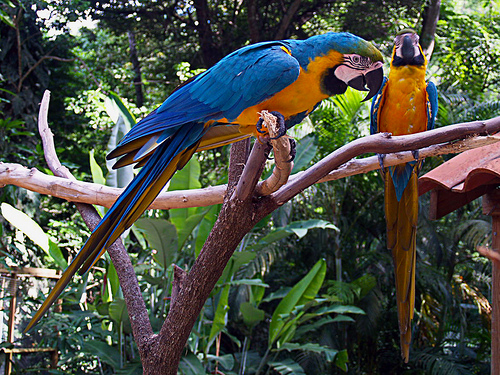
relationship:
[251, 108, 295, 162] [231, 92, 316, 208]
talons holding onto branch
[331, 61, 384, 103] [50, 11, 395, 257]
beak of parrott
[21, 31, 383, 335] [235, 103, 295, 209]
bird perched on branch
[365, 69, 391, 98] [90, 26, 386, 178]
beak on parrot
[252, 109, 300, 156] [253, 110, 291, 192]
feet wrapped around branch